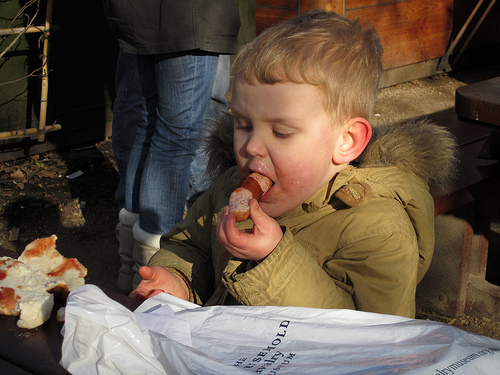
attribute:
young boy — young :
[135, 9, 460, 318]